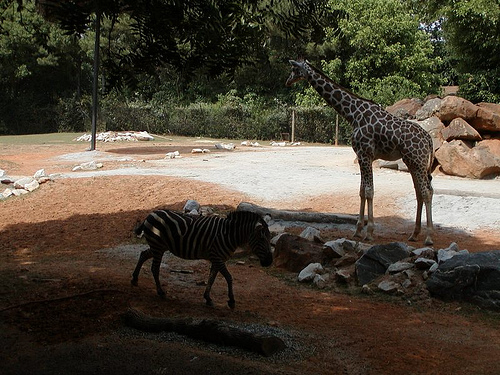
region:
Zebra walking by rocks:
[131, 203, 278, 307]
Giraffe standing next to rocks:
[282, 56, 446, 246]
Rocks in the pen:
[382, 93, 499, 178]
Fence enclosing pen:
[58, 96, 383, 144]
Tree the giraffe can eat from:
[32, 0, 139, 151]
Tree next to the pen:
[324, 10, 449, 140]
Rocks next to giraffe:
[181, 200, 498, 308]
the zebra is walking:
[113, 199, 275, 311]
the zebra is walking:
[103, 188, 295, 328]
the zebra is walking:
[118, 191, 277, 345]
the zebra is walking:
[106, 183, 294, 345]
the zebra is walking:
[119, 191, 291, 327]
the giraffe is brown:
[270, 18, 442, 252]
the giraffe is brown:
[254, 36, 454, 268]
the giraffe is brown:
[275, 45, 448, 258]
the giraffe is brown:
[270, 45, 461, 284]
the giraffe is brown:
[277, 43, 470, 263]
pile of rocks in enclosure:
[382, 99, 497, 177]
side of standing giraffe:
[285, 58, 435, 245]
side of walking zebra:
[130, 209, 271, 309]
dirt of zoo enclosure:
[2, 141, 499, 373]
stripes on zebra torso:
[163, 216, 220, 255]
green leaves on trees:
[2, 1, 497, 101]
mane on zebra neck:
[227, 208, 267, 225]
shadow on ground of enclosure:
[0, 205, 497, 373]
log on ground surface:
[120, 303, 286, 355]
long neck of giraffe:
[304, 63, 377, 121]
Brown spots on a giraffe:
[305, 69, 324, 87]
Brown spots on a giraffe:
[310, 67, 329, 89]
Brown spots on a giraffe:
[322, 78, 342, 96]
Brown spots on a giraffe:
[332, 89, 357, 112]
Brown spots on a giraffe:
[372, 99, 399, 135]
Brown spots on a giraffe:
[397, 121, 436, 155]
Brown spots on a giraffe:
[411, 157, 436, 182]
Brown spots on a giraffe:
[360, 139, 396, 169]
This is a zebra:
[125, 195, 305, 330]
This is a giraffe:
[283, 52, 460, 255]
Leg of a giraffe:
[362, 156, 382, 259]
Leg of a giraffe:
[354, 159, 369, 244]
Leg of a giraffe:
[422, 162, 444, 258]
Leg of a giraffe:
[408, 167, 425, 246]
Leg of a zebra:
[216, 257, 241, 316]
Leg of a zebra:
[202, 257, 221, 312]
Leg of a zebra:
[147, 245, 178, 302]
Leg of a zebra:
[129, 241, 154, 292]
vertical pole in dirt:
[86, 10, 102, 157]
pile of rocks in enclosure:
[379, 95, 497, 176]